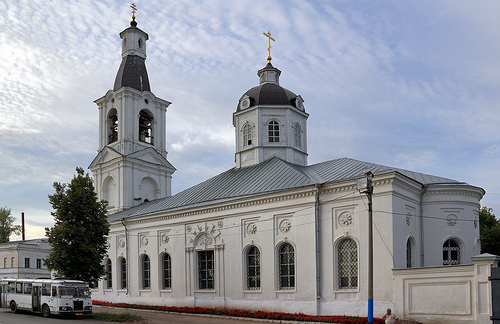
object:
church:
[108, 157, 420, 225]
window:
[332, 235, 357, 295]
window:
[278, 243, 292, 290]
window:
[246, 248, 259, 292]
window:
[198, 251, 215, 287]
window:
[161, 257, 170, 288]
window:
[139, 257, 149, 289]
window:
[117, 258, 128, 290]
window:
[104, 261, 111, 288]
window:
[408, 242, 415, 271]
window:
[444, 242, 457, 267]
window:
[267, 121, 280, 143]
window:
[294, 125, 302, 147]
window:
[242, 124, 253, 147]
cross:
[265, 31, 273, 62]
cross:
[129, 3, 136, 18]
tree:
[60, 189, 97, 272]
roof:
[257, 87, 291, 103]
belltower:
[114, 31, 150, 209]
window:
[138, 38, 144, 51]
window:
[122, 38, 128, 49]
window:
[140, 111, 151, 145]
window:
[108, 112, 118, 141]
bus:
[9, 279, 88, 314]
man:
[384, 309, 398, 322]